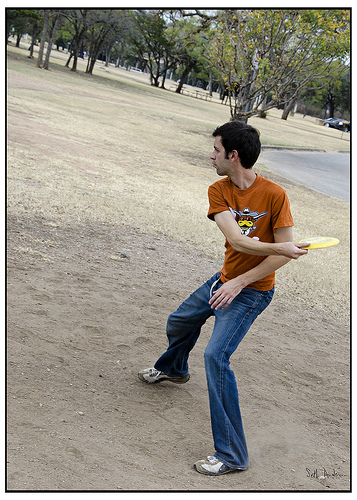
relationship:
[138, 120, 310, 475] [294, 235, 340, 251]
man playing frisbee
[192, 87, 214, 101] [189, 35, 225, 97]
picnic table under a tree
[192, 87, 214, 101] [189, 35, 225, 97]
picnic table under tree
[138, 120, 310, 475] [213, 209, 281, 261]
man has an arm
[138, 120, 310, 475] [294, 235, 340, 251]
man throws a frisbee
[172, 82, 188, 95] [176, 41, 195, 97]
picnic bench by tree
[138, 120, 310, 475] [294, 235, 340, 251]
man holding frisbee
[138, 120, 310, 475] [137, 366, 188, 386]
man has a shoe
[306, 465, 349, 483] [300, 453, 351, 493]
name in corner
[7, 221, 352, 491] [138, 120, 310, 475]
dirt under man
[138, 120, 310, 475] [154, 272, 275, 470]
man has pants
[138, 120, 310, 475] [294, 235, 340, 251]
man has a frisbee